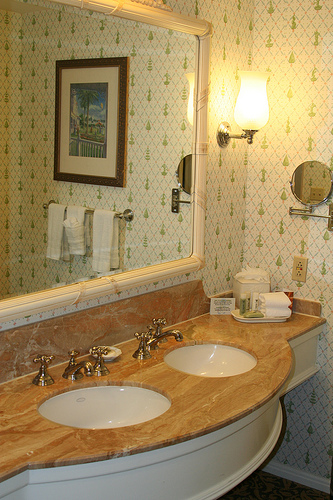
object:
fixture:
[32, 353, 54, 388]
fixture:
[88, 345, 111, 376]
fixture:
[132, 331, 152, 360]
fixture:
[148, 319, 168, 343]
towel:
[259, 304, 292, 319]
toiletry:
[245, 290, 251, 312]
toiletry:
[252, 291, 259, 312]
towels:
[255, 293, 289, 306]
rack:
[274, 289, 294, 321]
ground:
[239, 478, 306, 500]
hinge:
[289, 203, 319, 218]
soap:
[240, 310, 262, 317]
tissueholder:
[232, 273, 271, 308]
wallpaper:
[4, 1, 331, 322]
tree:
[287, 51, 296, 65]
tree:
[284, 90, 292, 100]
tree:
[280, 155, 290, 166]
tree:
[280, 191, 288, 201]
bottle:
[239, 294, 246, 315]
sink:
[37, 382, 171, 432]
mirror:
[0, 0, 200, 302]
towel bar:
[42, 199, 134, 220]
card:
[210, 297, 235, 315]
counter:
[0, 298, 326, 500]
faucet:
[145, 318, 184, 350]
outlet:
[291, 255, 307, 283]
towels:
[44, 199, 125, 274]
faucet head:
[62, 352, 93, 381]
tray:
[230, 306, 291, 322]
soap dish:
[89, 345, 123, 362]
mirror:
[288, 160, 333, 211]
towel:
[44, 202, 69, 261]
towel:
[59, 205, 88, 256]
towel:
[89, 208, 119, 273]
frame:
[51, 54, 130, 185]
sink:
[163, 339, 257, 376]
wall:
[1, 2, 332, 477]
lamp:
[215, 72, 269, 148]